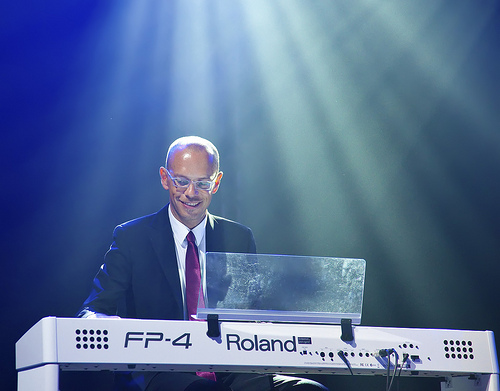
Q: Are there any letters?
A: Yes, there are letters.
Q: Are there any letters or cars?
A: Yes, there are letters.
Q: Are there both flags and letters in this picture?
A: No, there are letters but no flags.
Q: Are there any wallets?
A: No, there are no wallets.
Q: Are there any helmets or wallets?
A: No, there are no wallets or helmets.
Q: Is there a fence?
A: No, there are no fences.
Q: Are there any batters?
A: No, there are no batters.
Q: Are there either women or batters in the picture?
A: No, there are no batters or women.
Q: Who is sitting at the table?
A: The man is sitting at the table.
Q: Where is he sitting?
A: The man is sitting at the table.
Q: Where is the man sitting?
A: The man is sitting at the table.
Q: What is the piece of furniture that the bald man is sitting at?
A: The piece of furniture is a table.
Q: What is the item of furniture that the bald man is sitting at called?
A: The piece of furniture is a table.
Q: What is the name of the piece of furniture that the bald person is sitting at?
A: The piece of furniture is a table.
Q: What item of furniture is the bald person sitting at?
A: The man is sitting at the table.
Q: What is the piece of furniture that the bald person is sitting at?
A: The piece of furniture is a table.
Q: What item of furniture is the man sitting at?
A: The man is sitting at the table.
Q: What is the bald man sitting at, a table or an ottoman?
A: The man is sitting at a table.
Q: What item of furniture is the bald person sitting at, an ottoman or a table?
A: The man is sitting at a table.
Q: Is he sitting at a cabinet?
A: No, the man is sitting at the table.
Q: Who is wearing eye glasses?
A: The man is wearing eye glasses.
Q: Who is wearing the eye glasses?
A: The man is wearing eye glasses.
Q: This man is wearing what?
A: The man is wearing eyeglasses.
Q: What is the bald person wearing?
A: The man is wearing eyeglasses.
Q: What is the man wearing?
A: The man is wearing eyeglasses.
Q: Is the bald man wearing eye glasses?
A: Yes, the man is wearing eye glasses.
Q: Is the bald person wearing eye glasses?
A: Yes, the man is wearing eye glasses.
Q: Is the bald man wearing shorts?
A: No, the man is wearing eye glasses.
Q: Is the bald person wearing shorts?
A: No, the man is wearing eye glasses.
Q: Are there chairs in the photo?
A: No, there are no chairs.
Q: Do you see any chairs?
A: No, there are no chairs.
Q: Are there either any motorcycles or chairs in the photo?
A: No, there are no chairs or motorcycles.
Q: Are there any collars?
A: Yes, there is a collar.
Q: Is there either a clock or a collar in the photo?
A: Yes, there is a collar.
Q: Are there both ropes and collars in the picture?
A: No, there is a collar but no ropes.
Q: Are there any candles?
A: No, there are no candles.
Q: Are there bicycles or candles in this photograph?
A: No, there are no candles or bicycles.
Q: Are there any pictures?
A: No, there are no pictures.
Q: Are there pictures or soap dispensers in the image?
A: No, there are no pictures or soap dispensers.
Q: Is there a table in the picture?
A: Yes, there is a table.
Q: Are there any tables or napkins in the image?
A: Yes, there is a table.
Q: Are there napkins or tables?
A: Yes, there is a table.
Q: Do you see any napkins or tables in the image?
A: Yes, there is a table.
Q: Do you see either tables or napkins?
A: Yes, there is a table.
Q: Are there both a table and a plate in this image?
A: No, there is a table but no plates.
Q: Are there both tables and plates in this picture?
A: No, there is a table but no plates.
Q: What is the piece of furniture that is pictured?
A: The piece of furniture is a table.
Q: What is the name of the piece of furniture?
A: The piece of furniture is a table.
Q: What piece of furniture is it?
A: The piece of furniture is a table.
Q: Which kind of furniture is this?
A: This is a table.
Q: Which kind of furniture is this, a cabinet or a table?
A: This is a table.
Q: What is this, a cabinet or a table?
A: This is a table.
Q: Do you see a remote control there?
A: No, there are no remote controls.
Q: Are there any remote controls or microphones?
A: No, there are no remote controls or microphones.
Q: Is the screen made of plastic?
A: Yes, the screen is made of plastic.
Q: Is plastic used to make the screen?
A: Yes, the screen is made of plastic.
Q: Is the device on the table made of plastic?
A: Yes, the screen is made of plastic.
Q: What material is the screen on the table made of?
A: The screen is made of plastic.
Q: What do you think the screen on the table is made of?
A: The screen is made of plastic.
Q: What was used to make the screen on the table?
A: The screen is made of plastic.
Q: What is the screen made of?
A: The screen is made of plastic.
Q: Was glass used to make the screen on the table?
A: No, the screen is made of plastic.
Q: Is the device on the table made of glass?
A: No, the screen is made of plastic.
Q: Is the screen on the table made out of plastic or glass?
A: The screen is made of plastic.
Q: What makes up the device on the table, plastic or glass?
A: The screen is made of plastic.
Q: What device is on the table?
A: The device is a screen.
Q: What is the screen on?
A: The screen is on the table.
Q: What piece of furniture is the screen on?
A: The screen is on the table.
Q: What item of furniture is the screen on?
A: The screen is on the table.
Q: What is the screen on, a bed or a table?
A: The screen is on a table.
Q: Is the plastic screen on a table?
A: Yes, the screen is on a table.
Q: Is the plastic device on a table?
A: Yes, the screen is on a table.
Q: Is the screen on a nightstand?
A: No, the screen is on a table.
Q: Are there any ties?
A: Yes, there is a tie.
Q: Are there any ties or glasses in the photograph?
A: Yes, there is a tie.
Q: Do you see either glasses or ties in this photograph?
A: Yes, there is a tie.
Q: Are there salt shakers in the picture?
A: No, there are no salt shakers.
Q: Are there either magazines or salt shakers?
A: No, there are no salt shakers or magazines.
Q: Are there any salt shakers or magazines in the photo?
A: No, there are no salt shakers or magazines.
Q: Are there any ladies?
A: No, there are no ladies.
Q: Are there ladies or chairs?
A: No, there are no ladies or chairs.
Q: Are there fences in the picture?
A: No, there are no fences.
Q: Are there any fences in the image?
A: No, there are no fences.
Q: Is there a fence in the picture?
A: No, there are no fences.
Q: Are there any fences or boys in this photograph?
A: No, there are no fences or boys.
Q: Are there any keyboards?
A: Yes, there is a keyboard.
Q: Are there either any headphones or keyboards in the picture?
A: Yes, there is a keyboard.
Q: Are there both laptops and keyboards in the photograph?
A: No, there is a keyboard but no laptops.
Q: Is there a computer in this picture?
A: No, there are no computers.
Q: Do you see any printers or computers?
A: No, there are no computers or printers.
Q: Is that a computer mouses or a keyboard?
A: That is a keyboard.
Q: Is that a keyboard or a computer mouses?
A: That is a keyboard.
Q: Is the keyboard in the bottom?
A: Yes, the keyboard is in the bottom of the image.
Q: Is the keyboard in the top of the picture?
A: No, the keyboard is in the bottom of the image.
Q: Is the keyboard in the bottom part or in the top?
A: The keyboard is in the bottom of the image.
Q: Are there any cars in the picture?
A: No, there are no cars.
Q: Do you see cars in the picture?
A: No, there are no cars.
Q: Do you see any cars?
A: No, there are no cars.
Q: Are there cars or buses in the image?
A: No, there are no cars or buses.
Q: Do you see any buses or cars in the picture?
A: No, there are no cars or buses.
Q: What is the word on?
A: The word is on the table.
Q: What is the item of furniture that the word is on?
A: The piece of furniture is a table.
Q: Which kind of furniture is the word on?
A: The word is on the table.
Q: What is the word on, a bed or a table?
A: The word is on a table.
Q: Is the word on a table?
A: Yes, the word is on a table.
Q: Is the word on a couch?
A: No, the word is on a table.